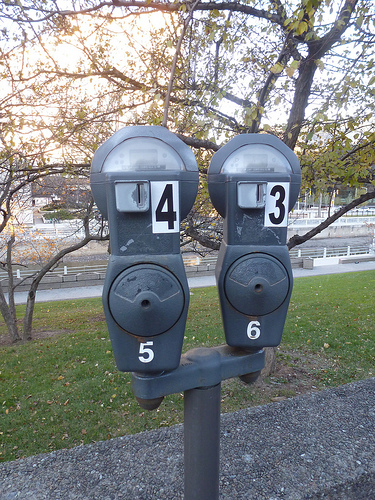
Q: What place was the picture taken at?
A: It was taken at the sidewalk.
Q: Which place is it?
A: It is a sidewalk.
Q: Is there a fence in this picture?
A: Yes, there is a fence.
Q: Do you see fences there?
A: Yes, there is a fence.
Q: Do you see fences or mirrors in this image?
A: Yes, there is a fence.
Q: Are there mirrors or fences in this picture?
A: Yes, there is a fence.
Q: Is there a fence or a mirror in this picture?
A: Yes, there is a fence.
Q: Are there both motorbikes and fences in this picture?
A: No, there is a fence but no motorcycles.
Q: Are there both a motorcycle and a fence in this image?
A: No, there is a fence but no motorcycles.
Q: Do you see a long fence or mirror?
A: Yes, there is a long fence.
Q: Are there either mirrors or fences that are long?
A: Yes, the fence is long.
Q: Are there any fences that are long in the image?
A: Yes, there is a long fence.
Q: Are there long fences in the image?
A: Yes, there is a long fence.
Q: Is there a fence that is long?
A: Yes, there is a fence that is long.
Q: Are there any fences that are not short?
A: Yes, there is a long fence.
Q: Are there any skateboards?
A: No, there are no skateboards.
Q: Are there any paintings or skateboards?
A: No, there are no skateboards or paintings.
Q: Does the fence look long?
A: Yes, the fence is long.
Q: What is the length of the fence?
A: The fence is long.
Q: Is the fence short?
A: No, the fence is long.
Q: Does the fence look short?
A: No, the fence is long.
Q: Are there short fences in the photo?
A: No, there is a fence but it is long.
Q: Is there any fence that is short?
A: No, there is a fence but it is long.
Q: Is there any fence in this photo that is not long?
A: No, there is a fence but it is long.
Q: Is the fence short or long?
A: The fence is long.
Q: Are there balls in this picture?
A: No, there are no balls.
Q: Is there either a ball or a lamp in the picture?
A: No, there are no balls or lamps.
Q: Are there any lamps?
A: No, there are no lamps.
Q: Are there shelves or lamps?
A: No, there are no lamps or shelves.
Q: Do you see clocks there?
A: No, there are no clocks.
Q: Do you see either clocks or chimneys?
A: No, there are no clocks or chimneys.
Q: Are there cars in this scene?
A: No, there are no cars.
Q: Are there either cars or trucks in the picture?
A: No, there are no cars or trucks.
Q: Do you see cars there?
A: No, there are no cars.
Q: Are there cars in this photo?
A: No, there are no cars.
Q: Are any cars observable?
A: No, there are no cars.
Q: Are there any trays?
A: No, there are no trays.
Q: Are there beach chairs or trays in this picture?
A: No, there are no trays or beach chairs.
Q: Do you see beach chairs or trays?
A: No, there are no trays or beach chairs.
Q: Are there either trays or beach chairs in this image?
A: No, there are no trays or beach chairs.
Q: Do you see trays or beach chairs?
A: No, there are no trays or beach chairs.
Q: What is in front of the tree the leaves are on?
A: The machine is in front of the tree.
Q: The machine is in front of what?
A: The machine is in front of the tree.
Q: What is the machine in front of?
A: The machine is in front of the tree.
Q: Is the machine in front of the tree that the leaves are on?
A: Yes, the machine is in front of the tree.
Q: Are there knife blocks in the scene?
A: No, there are no knife blocks.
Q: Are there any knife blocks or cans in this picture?
A: No, there are no knife blocks or cans.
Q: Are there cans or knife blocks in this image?
A: No, there are no knife blocks or cans.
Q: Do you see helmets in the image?
A: No, there are no helmets.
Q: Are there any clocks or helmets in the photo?
A: No, there are no helmets or clocks.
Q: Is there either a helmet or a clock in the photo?
A: No, there are no helmets or clocks.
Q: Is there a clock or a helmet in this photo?
A: No, there are no helmets or clocks.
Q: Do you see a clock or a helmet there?
A: No, there are no helmets or clocks.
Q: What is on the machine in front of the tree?
A: The number is on the machine.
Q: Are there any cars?
A: No, there are no cars.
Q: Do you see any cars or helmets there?
A: No, there are no cars or helmets.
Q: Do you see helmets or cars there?
A: No, there are no cars or helmets.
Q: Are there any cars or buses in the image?
A: No, there are no buses or cars.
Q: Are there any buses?
A: No, there are no buses.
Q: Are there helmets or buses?
A: No, there are no buses or helmets.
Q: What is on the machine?
A: The number is on the machine.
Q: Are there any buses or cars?
A: No, there are no cars or buses.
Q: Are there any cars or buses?
A: No, there are no cars or buses.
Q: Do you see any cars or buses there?
A: No, there are no cars or buses.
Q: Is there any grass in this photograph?
A: Yes, there is grass.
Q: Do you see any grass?
A: Yes, there is grass.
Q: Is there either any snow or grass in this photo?
A: Yes, there is grass.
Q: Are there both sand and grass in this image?
A: No, there is grass but no sand.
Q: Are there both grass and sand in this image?
A: No, there is grass but no sand.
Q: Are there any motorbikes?
A: No, there are no motorbikes.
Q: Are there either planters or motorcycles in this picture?
A: No, there are no motorcycles or planters.